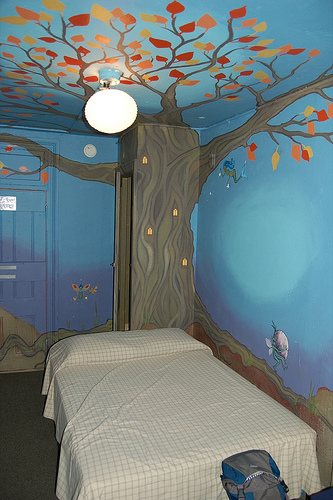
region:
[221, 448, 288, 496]
Backpack leaning against the bed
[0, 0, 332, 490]
Painted mural on walls and ceiling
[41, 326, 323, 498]
Mattress on the floor with checkered bedspread.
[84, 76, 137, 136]
Light hanging from ceiling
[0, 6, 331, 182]
Leaves on the tree's branches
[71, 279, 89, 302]
Butterfly painted on the wall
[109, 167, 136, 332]
Slightly opened closet door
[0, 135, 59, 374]
Painted door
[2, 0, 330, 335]
Tree mural on walls and ceiling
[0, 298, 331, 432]
Painted roots of the tree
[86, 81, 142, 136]
The round light above the bed.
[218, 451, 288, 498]
The bag in front of the bed.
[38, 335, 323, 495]
The sheet on the bed.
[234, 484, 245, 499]
The left snap of the bag.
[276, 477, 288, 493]
The right snap of the bag.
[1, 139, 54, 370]
The door in the room.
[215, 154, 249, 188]
The mermaid painted on the wall on the right.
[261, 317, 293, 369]
The alien painted on the wall to the right of the bed.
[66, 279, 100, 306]
The butterfly fairy painted on the wall above the pillow area of the bed.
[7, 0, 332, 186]
The leaves of the tree painted on the walls.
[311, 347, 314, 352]
side of a wall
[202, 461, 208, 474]
edge of a bed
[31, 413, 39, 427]
part of a floor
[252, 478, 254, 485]
side of a bag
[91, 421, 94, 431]
part of a sheet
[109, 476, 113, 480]
edge of a bed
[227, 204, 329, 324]
this is the wall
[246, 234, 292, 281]
the wall is blue in color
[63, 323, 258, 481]
this is a bed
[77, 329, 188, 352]
this is a pillow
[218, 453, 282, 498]
this is a bag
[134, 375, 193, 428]
this is a bedcover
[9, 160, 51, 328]
this is is a door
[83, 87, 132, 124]
this is a light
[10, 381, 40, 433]
this is the floor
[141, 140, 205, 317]
this is a tree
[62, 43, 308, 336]
a tree paintedon the wall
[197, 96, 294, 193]
leaves painted on the wall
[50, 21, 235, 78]
leaves painted on the ceiling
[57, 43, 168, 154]
a light on a ceiling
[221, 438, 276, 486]
a backpack on the floor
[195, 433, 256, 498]
a backpack against a bed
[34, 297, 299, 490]
a bed ina room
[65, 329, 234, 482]
a small bed in a room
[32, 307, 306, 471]
a room with a bed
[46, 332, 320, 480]
a bed that is mad